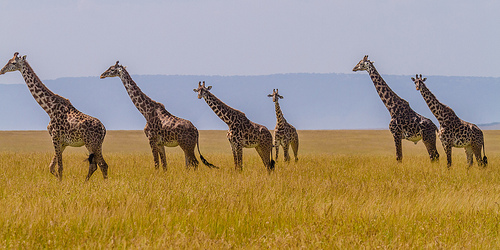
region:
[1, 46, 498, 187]
a field of giraffe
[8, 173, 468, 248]
tall grass in the field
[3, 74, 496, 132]
a mountain behind the giraffe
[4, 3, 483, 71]
the sky above the mountains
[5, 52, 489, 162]
six giraffe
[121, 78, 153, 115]
the neck of the giraffe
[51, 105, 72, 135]
spots on the giraffe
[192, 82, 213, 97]
the face of the giraffe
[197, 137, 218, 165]
the tail of the giraffe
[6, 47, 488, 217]
giraffe standing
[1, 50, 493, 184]
a herd of giraffes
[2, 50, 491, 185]
six giraffes in a yellow field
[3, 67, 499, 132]
grey hills in the background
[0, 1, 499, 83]
hazy blue sky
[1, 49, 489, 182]
five giraffes are facing left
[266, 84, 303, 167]
one giraffe is facing forward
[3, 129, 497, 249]
grass is long and yellow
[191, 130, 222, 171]
long giraffe tail with a dark end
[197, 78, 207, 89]
small horns on a giraffe head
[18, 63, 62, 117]
long patterned brown and beige neck of a giraffe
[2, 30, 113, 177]
giraffe in the field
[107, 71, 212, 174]
giraffe in the field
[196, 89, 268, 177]
giraffe in the field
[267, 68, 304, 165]
giraffe in the field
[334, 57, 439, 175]
giraffe in the field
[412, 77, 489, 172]
giraffe in the field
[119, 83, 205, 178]
giraffe in the field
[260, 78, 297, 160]
giraffe in the field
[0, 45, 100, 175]
giraffe in the field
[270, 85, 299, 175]
giraffe in the field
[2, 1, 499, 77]
the blue sky above everything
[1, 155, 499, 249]
the tall green grass for the animals to stand in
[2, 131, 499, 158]
the empty field next to the grass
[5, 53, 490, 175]
a small herd of giraffes standing in a field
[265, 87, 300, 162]
the giraffe standing towards the camera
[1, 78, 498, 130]
a mountain behind the giraffes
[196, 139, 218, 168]
a tail on the giraffe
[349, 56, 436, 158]
the tallest of the giraffes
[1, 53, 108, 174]
the giraffe in the lead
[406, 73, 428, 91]
the giraffe looking at the camera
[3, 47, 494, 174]
Six giraffes standing near one another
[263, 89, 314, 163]
Giraffe looking towards camera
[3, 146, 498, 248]
Yellow grass covering the ground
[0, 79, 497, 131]
Mountains can be seen in the distance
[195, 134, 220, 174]
Tail of giraffe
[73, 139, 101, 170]
Giraffe's tail is between its legs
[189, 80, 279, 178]
Giraffe holding head down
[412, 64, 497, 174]
Giraffe looking towards camera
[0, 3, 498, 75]
Sky can be seen above the mountains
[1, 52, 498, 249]
giraffes grazing on a field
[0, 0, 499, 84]
Sky is white and hazey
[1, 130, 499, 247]
grass is very dry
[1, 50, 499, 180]
group of tall giraffes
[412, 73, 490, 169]
black and cream giraffe standing in a grassy field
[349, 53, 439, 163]
black and cream giraffe standing in a grassy field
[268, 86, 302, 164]
black and cream giraffe standing in a grassy field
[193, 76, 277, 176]
black and cream giraffe standing in a grassy field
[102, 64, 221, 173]
black and cream giraffe standing in a grassy field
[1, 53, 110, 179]
black and cream giraffe standing in a grassy field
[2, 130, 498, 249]
field full of tan and green grasses